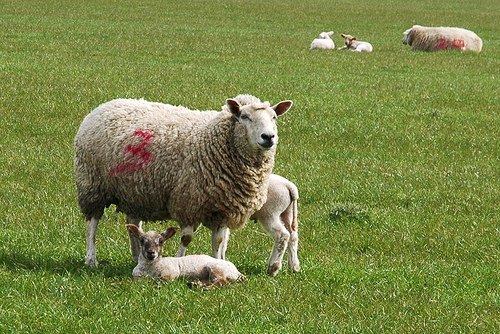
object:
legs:
[83, 193, 103, 256]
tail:
[288, 186, 300, 231]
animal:
[223, 174, 301, 277]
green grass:
[352, 276, 497, 334]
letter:
[432, 33, 464, 49]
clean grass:
[327, 75, 487, 319]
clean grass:
[13, 9, 275, 85]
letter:
[109, 129, 156, 176]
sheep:
[68, 91, 293, 267]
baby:
[124, 223, 248, 290]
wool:
[133, 117, 218, 191]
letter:
[330, 206, 370, 224]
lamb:
[308, 31, 336, 51]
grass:
[0, 0, 83, 334]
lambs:
[336, 33, 373, 53]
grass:
[296, 76, 439, 163]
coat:
[72, 94, 277, 230]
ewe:
[400, 24, 483, 53]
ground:
[306, 91, 500, 334]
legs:
[210, 226, 226, 261]